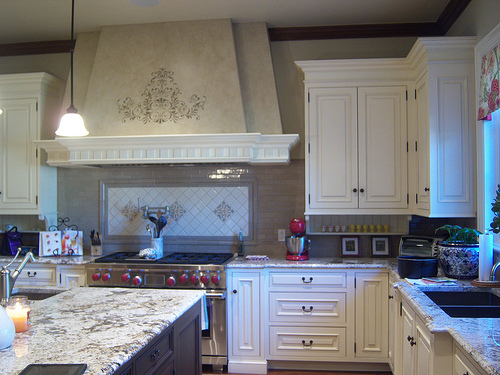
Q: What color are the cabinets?
A: White.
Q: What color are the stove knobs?
A: Red.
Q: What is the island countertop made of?
A: Marble.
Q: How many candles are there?
A: One.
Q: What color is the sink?
A: Black.